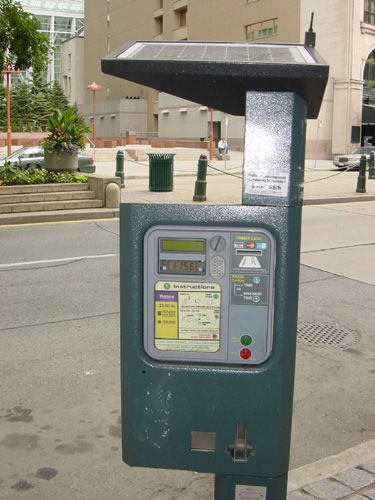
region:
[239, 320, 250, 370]
There are red and green buttons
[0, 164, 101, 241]
There are stairs in the background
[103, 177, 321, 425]
there is a parking meter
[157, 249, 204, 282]
Tells you what time it is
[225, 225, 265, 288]
There is a card slot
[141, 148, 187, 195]
There is a trash can on the sidewalk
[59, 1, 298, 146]
there is a building in the background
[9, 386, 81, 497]
The street is wet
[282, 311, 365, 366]
There is a sewer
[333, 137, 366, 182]
There is a silver car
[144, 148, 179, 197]
a green public trashcan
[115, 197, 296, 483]
an electric parking meter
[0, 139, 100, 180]
A parked green car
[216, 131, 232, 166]
a person sitting in a public area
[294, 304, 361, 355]
sewer grate in the road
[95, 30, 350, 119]
a solar panel that powers the meter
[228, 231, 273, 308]
the place where money is inserted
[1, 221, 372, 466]
a city road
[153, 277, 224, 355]
the meter's instructions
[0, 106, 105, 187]
plotted plants on the side of a city road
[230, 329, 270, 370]
Buttons on the box.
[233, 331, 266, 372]
Red and green buttons.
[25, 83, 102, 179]
Plant in cement planter.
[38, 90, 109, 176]
Green plant in the planter.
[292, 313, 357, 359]
Drain on the city street.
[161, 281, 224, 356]
Instructions on the green box.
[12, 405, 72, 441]
Stains on the city street.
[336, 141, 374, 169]
Car by the building.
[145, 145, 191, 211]
Green trashcan on the sidewalk.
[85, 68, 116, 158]
Street light on the sidewalk.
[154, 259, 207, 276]
11:56 on a digital clock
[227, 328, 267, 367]
a red and a green button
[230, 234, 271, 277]
a slot for credit cards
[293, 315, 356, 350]
a man hole cover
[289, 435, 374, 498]
a stone sidewalk and a curb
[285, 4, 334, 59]
an antenna for radio waves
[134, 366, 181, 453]
some scrapped area on the unit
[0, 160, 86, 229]
stone steps next to a planter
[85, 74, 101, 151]
an outdoor light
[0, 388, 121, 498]
stains on the street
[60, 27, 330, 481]
old parking meter in front of plaza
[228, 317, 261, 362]
green and red button on panel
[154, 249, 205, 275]
current time showing through window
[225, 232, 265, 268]
horizontal metal payment slot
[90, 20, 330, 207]
solar panel hanging above parking meter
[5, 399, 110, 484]
oily stains on street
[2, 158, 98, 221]
steps leading to plantings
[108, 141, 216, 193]
garbage can between two pillars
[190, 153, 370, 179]
curved chain linking two pillars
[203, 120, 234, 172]
person seated on steps